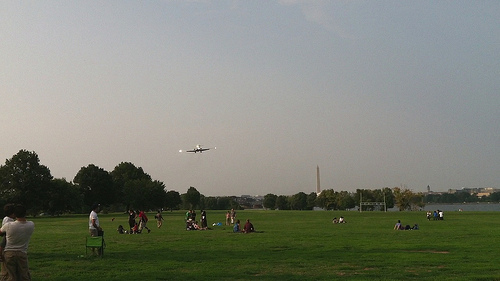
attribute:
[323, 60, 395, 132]
clouds — white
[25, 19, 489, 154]
sky — blue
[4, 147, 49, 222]
tree — green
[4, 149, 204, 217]
leaves — green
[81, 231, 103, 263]
chair — green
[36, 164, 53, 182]
leaves — green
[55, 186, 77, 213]
leaves — green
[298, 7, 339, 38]
cloud — white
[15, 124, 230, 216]
tree — green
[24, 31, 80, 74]
sky — blue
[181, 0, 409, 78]
clouds — white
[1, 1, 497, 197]
sky — blue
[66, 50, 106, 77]
clouds — white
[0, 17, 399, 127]
clouds — white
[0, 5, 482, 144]
sky — blue